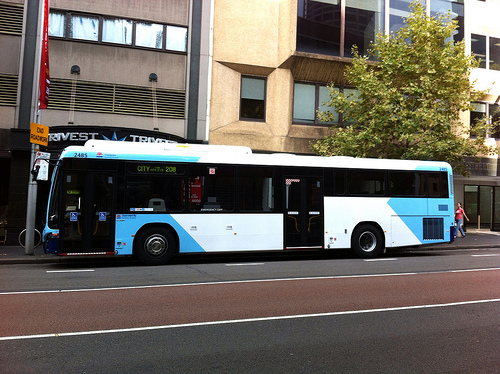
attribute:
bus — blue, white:
[18, 135, 460, 268]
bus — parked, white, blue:
[31, 139, 456, 263]